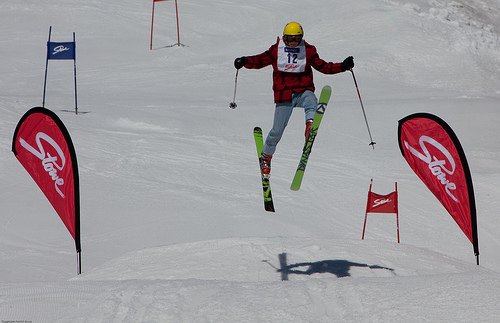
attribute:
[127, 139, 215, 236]
snow — white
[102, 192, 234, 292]
snow — white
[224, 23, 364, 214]
person — skiing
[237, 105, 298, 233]
ski — black, white, long, green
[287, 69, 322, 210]
ski — green, long, black, white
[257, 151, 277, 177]
boot — red, plastic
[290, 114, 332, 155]
boot — plastic, red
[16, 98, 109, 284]
flag — red, black, white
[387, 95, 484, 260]
flag — white, red, black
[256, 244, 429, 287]
shadow — dark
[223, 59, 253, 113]
pole — black, long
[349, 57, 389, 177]
pole — long, black